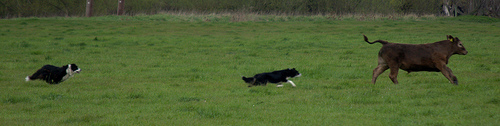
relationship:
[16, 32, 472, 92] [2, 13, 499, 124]
animals running in field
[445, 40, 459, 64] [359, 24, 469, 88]
neck of a cow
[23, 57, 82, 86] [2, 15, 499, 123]
dog jumping off ground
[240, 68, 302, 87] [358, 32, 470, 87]
animals chasing cow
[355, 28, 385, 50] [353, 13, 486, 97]
tail of cow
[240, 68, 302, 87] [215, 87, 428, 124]
animals on field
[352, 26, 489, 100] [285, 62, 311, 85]
cow has eye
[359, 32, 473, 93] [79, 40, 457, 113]
animal in field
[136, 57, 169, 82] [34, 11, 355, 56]
grass in field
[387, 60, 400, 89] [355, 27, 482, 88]
leg of cow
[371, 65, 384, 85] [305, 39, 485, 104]
leg of cow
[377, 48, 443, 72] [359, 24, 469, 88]
body of cow